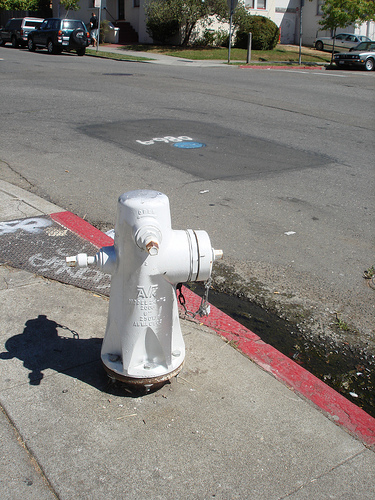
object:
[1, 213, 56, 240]
spray paint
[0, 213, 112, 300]
metal grate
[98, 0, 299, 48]
house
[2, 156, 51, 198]
crack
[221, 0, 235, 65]
sign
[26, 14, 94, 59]
cars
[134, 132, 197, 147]
marking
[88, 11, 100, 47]
person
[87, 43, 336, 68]
sidewalk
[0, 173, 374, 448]
curb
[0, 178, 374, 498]
sidewalk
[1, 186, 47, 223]
crack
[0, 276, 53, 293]
crack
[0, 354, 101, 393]
crack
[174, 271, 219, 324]
chain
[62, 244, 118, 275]
knob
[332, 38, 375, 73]
car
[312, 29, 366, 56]
car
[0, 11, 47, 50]
car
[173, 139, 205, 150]
blue cover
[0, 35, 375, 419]
road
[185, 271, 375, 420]
puddle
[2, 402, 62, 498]
sidewalk line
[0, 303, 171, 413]
shadow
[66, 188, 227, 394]
fire hydrant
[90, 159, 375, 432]
roadside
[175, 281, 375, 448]
line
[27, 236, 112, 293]
graffiti